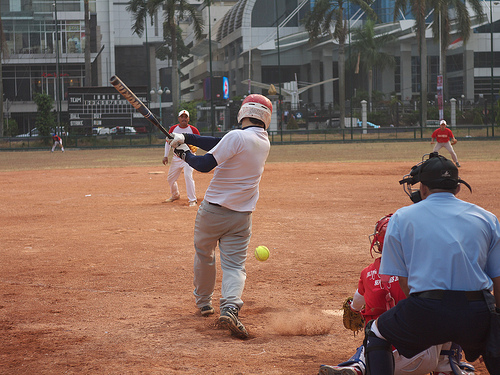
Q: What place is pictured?
A: It is a park.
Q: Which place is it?
A: It is a park.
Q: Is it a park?
A: Yes, it is a park.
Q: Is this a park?
A: Yes, it is a park.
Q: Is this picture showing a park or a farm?
A: It is showing a park.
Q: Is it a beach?
A: No, it is a park.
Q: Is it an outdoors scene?
A: Yes, it is outdoors.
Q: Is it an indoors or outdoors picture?
A: It is outdoors.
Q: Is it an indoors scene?
A: No, it is outdoors.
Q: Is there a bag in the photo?
A: No, there are no bags.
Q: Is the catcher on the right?
A: Yes, the catcher is on the right of the image.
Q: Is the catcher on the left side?
A: No, the catcher is on the right of the image.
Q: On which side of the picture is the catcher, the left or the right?
A: The catcher is on the right of the image.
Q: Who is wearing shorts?
A: The catcher is wearing shorts.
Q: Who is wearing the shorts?
A: The catcher is wearing shorts.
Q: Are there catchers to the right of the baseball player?
A: Yes, there is a catcher to the right of the player.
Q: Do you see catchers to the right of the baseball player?
A: Yes, there is a catcher to the right of the player.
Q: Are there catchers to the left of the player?
A: No, the catcher is to the right of the player.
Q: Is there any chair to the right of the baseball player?
A: No, there is a catcher to the right of the player.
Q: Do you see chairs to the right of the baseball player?
A: No, there is a catcher to the right of the player.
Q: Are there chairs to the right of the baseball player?
A: No, there is a catcher to the right of the player.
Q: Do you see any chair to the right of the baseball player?
A: No, there is a catcher to the right of the player.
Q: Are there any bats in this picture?
A: Yes, there is a bat.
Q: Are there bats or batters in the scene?
A: Yes, there is a bat.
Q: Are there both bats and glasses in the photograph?
A: No, there is a bat but no glasses.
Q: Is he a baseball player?
A: Yes, this is a baseball player.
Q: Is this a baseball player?
A: Yes, this is a baseball player.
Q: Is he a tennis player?
A: No, this is a baseball player.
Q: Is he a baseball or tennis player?
A: This is a baseball player.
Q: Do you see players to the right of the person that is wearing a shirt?
A: Yes, there is a player to the right of the person.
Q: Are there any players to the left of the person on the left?
A: No, the player is to the right of the person.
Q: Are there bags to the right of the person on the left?
A: No, there is a player to the right of the person.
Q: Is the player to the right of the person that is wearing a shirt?
A: Yes, the player is to the right of the person.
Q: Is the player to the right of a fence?
A: No, the player is to the right of the person.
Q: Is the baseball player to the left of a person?
A: No, the player is to the right of a person.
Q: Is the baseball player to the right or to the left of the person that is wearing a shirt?
A: The player is to the right of the person.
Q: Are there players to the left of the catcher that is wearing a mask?
A: Yes, there is a player to the left of the catcher.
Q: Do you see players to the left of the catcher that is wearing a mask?
A: Yes, there is a player to the left of the catcher.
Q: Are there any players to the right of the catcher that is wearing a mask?
A: No, the player is to the left of the catcher.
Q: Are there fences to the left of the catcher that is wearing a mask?
A: No, there is a player to the left of the catcher.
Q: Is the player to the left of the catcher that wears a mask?
A: Yes, the player is to the left of the catcher.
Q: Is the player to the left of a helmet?
A: No, the player is to the left of the catcher.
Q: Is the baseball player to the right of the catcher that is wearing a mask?
A: No, the player is to the left of the catcher.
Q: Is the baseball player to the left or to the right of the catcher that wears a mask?
A: The player is to the left of the catcher.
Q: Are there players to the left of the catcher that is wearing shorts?
A: Yes, there is a player to the left of the catcher.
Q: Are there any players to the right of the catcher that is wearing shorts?
A: No, the player is to the left of the catcher.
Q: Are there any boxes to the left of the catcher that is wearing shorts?
A: No, there is a player to the left of the catcher.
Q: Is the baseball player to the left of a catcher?
A: Yes, the player is to the left of a catcher.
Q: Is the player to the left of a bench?
A: No, the player is to the left of a catcher.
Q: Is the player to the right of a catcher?
A: No, the player is to the left of a catcher.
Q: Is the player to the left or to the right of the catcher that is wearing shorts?
A: The player is to the left of the catcher.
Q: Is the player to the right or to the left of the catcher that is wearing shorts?
A: The player is to the left of the catcher.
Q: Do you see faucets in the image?
A: No, there are no faucets.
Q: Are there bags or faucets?
A: No, there are no faucets or bags.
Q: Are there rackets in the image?
A: No, there are no rackets.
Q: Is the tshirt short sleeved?
A: Yes, the tshirt is short sleeved.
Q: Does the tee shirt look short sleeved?
A: Yes, the tee shirt is short sleeved.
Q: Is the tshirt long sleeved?
A: No, the tshirt is short sleeved.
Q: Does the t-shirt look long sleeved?
A: No, the t-shirt is short sleeved.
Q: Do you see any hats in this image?
A: Yes, there is a hat.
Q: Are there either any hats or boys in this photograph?
A: Yes, there is a hat.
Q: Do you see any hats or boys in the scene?
A: Yes, there is a hat.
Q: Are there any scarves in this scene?
A: No, there are no scarves.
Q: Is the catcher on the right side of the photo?
A: Yes, the catcher is on the right of the image.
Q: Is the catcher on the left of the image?
A: No, the catcher is on the right of the image.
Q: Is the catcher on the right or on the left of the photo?
A: The catcher is on the right of the image.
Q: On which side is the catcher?
A: The catcher is on the right of the image.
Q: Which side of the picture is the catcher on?
A: The catcher is on the right of the image.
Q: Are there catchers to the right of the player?
A: Yes, there is a catcher to the right of the player.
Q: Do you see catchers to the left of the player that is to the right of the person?
A: No, the catcher is to the right of the player.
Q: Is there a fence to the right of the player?
A: No, there is a catcher to the right of the player.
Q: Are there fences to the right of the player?
A: No, there is a catcher to the right of the player.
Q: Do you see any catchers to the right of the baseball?
A: Yes, there is a catcher to the right of the baseball.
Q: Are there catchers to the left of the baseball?
A: No, the catcher is to the right of the baseball.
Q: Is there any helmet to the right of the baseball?
A: No, there is a catcher to the right of the baseball.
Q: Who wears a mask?
A: The catcher wears a mask.